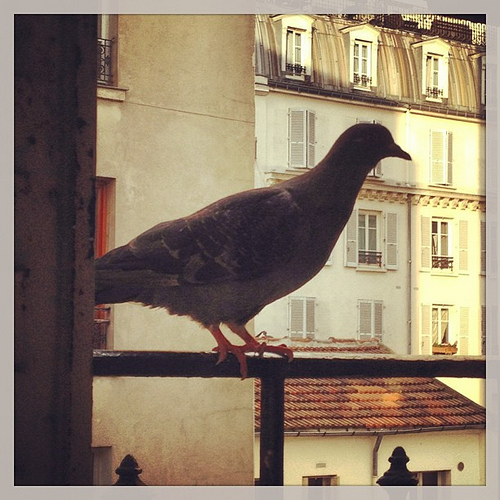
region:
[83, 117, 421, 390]
pigeon balancing on a railing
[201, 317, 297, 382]
pink legs and feet of a pigeon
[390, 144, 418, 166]
beak on a pigeon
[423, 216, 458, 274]
window behind a small balcony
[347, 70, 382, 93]
railings outside a small window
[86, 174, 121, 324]
red window frame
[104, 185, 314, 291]
wing of a pigeon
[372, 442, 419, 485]
metal top of a post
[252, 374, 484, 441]
red roof tiles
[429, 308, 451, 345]
curtains behind a window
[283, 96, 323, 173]
window with closed shutters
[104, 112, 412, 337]
a grey pigeon in a window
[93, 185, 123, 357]
a red edge of a window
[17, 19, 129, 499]
a portion of the window frame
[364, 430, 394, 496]
a rain downspout from the lower roof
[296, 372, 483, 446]
terra-cotta tiles roof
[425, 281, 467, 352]
partially pulled back white curtain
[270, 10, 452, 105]
three dormors on the neighboring rooftop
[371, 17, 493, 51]
wrought iron railing on the rooftop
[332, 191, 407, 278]
open shuttered window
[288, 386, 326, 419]
brown tile roof on house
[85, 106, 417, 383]
pigeon standing on rail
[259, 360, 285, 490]
metal guard rail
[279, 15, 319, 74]
window on side of building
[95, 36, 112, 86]
black metal guard railing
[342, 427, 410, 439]
silver metal rain gutters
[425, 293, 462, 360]
open window with white curtains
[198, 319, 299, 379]
orange bird feet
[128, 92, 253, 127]
seam on side of building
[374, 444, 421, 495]
design on post on side of building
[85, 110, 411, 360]
this is a bird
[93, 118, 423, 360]
the bird is big in size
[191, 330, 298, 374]
the feet are on the stand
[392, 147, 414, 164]
this is the beak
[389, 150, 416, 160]
the beak is short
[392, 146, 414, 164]
the beak is sharp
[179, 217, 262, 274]
the feathers are folded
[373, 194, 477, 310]
this is a house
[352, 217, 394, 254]
the window is open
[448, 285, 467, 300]
the wall is white in color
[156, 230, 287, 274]
this is the bird's wing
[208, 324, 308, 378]
these are the bird's feet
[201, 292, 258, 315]
the feathers are white in color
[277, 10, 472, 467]
this is a building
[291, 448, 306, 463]
the wall is white in color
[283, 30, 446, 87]
these are the windows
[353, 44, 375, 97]
the window is closed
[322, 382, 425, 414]
this is a roof